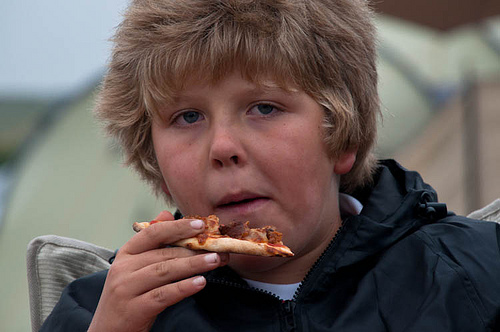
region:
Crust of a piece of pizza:
[134, 213, 294, 258]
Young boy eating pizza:
[39, 1, 499, 330]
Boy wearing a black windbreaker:
[28, 0, 497, 327]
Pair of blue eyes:
[164, 99, 290, 128]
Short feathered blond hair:
[93, 0, 382, 203]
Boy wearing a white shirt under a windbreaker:
[44, 1, 498, 329]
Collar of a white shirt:
[172, 192, 367, 302]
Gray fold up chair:
[23, 198, 497, 329]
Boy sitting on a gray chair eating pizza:
[22, 0, 493, 329]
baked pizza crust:
[131, 218, 293, 262]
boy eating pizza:
[113, 36, 400, 291]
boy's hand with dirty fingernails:
[176, 213, 218, 298]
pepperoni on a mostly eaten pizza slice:
[214, 219, 244, 236]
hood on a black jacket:
[347, 149, 444, 234]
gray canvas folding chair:
[20, 190, 498, 329]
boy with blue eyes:
[170, 100, 284, 122]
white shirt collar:
[236, 270, 311, 302]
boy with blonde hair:
[90, 0, 392, 227]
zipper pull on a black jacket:
[276, 292, 305, 330]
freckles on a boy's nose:
[204, 128, 241, 143]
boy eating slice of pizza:
[92, 13, 460, 298]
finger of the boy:
[185, 271, 214, 297]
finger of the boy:
[200, 251, 220, 269]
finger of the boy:
[171, 215, 198, 236]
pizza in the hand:
[218, 218, 287, 260]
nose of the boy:
[200, 146, 255, 171]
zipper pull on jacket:
[272, 293, 335, 313]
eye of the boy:
[245, 100, 281, 120]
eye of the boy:
[171, 103, 203, 134]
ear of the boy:
[328, 146, 378, 182]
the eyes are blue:
[162, 87, 303, 132]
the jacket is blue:
[370, 159, 452, 330]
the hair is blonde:
[167, 20, 336, 78]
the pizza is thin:
[216, 227, 293, 260]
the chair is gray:
[45, 246, 101, 278]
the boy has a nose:
[198, 135, 282, 170]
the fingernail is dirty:
[197, 250, 226, 272]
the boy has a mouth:
[205, 180, 271, 213]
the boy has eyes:
[165, 98, 313, 136]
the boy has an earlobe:
[327, 151, 355, 179]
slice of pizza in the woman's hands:
[132, 217, 298, 254]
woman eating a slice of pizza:
[36, 3, 496, 330]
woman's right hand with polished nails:
[86, 210, 221, 330]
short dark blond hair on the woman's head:
[100, 4, 375, 195]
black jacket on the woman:
[40, 157, 495, 329]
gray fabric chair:
[25, 227, 116, 330]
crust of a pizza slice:
[125, 222, 293, 259]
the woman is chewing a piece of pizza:
[31, 1, 498, 328]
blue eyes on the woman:
[172, 101, 286, 123]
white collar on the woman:
[238, 189, 366, 300]